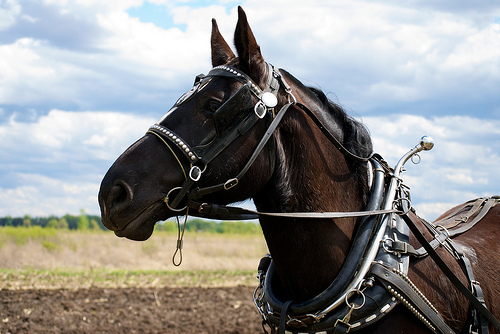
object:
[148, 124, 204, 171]
leather strip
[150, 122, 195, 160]
studs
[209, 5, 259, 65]
ear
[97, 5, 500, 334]
brown horse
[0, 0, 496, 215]
clouds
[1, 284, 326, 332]
dirt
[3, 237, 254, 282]
field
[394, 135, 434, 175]
chrome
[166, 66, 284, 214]
straps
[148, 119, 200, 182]
straps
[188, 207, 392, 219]
straps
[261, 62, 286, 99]
straps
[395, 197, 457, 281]
straps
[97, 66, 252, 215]
horse face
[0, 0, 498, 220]
sky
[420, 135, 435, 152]
ball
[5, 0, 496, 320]
foreground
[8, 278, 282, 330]
ground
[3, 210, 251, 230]
trees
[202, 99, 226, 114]
eye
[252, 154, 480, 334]
rigging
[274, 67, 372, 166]
mane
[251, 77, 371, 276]
neck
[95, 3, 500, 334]
horse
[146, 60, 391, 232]
straps